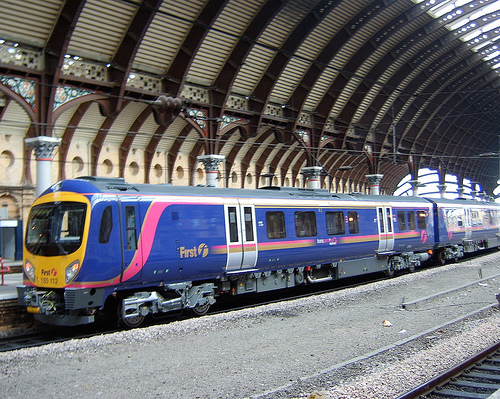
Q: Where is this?
A: This is at the pavement.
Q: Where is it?
A: This is at the pavement.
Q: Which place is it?
A: It is a pavement.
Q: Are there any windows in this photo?
A: Yes, there is a window.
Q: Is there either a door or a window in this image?
A: Yes, there is a window.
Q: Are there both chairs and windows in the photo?
A: No, there is a window but no chairs.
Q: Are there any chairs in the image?
A: No, there are no chairs.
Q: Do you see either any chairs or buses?
A: No, there are no chairs or buses.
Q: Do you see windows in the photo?
A: Yes, there is a window.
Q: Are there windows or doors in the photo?
A: Yes, there is a window.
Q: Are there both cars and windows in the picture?
A: Yes, there are both a window and a car.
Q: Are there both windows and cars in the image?
A: Yes, there are both a window and a car.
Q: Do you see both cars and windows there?
A: Yes, there are both a window and a car.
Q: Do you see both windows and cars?
A: Yes, there are both a window and a car.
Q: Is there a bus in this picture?
A: No, there are no buses.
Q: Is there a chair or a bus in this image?
A: No, there are no buses or chairs.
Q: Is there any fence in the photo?
A: No, there are no fences.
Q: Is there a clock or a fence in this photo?
A: No, there are no fences or clocks.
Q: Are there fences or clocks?
A: No, there are no fences or clocks.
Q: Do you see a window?
A: Yes, there is a window.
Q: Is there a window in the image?
A: Yes, there is a window.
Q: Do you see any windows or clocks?
A: Yes, there is a window.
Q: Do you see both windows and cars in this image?
A: Yes, there are both a window and a car.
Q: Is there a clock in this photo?
A: No, there are no clocks.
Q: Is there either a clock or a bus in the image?
A: No, there are no clocks or buses.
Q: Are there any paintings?
A: No, there are no paintings.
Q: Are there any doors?
A: Yes, there are doors.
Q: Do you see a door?
A: Yes, there are doors.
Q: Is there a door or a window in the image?
A: Yes, there are doors.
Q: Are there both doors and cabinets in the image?
A: No, there are doors but no cabinets.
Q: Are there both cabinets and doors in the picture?
A: No, there are doors but no cabinets.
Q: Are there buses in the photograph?
A: No, there are no buses.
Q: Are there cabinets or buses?
A: No, there are no buses or cabinets.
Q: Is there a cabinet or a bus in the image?
A: No, there are no buses or cabinets.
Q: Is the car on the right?
A: Yes, the car is on the right of the image.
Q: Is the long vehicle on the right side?
A: Yes, the car is on the right of the image.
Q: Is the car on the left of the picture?
A: No, the car is on the right of the image.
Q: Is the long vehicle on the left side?
A: No, the car is on the right of the image.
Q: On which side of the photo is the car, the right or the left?
A: The car is on the right of the image.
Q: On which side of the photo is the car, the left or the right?
A: The car is on the right of the image.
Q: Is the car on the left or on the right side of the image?
A: The car is on the right of the image.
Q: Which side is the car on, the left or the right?
A: The car is on the right of the image.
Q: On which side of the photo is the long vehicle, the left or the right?
A: The car is on the right of the image.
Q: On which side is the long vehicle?
A: The car is on the right of the image.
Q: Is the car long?
A: Yes, the car is long.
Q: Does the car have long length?
A: Yes, the car is long.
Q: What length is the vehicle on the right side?
A: The car is long.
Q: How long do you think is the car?
A: The car is long.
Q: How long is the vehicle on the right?
A: The car is long.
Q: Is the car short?
A: No, the car is long.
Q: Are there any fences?
A: No, there are no fences.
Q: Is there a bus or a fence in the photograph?
A: No, there are no fences or buses.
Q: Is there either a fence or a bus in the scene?
A: No, there are no fences or buses.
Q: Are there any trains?
A: Yes, there is a train.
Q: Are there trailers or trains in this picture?
A: Yes, there is a train.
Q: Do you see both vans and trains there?
A: No, there is a train but no vans.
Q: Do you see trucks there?
A: No, there are no trucks.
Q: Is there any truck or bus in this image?
A: No, there are no trucks or buses.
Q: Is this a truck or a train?
A: This is a train.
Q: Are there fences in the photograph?
A: No, there are no fences.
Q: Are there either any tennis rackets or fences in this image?
A: No, there are no fences or tennis rackets.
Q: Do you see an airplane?
A: No, there are no airplanes.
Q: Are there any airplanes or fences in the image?
A: No, there are no airplanes or fences.